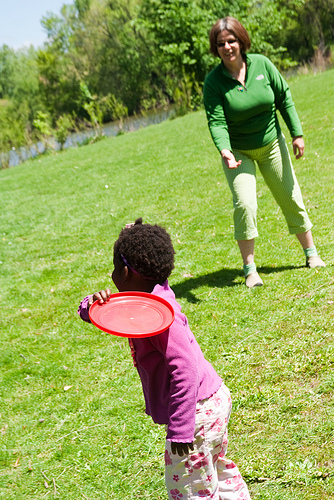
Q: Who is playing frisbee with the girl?
A: A woman.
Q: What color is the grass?
A: Green.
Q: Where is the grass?
A: On the ground.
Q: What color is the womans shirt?
A: Green.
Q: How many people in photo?
A: Two.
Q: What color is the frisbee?
A: Red.